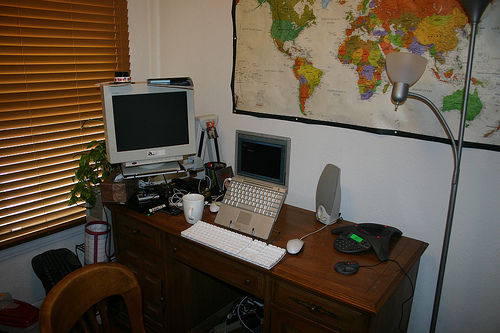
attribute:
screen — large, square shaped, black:
[108, 88, 193, 160]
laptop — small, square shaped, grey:
[213, 117, 298, 238]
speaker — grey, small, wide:
[312, 159, 342, 228]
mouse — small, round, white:
[284, 239, 307, 259]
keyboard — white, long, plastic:
[179, 210, 295, 280]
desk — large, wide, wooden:
[104, 192, 433, 332]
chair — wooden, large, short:
[15, 250, 151, 330]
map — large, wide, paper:
[222, 3, 498, 164]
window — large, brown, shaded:
[1, 1, 153, 255]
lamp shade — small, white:
[390, 50, 430, 88]